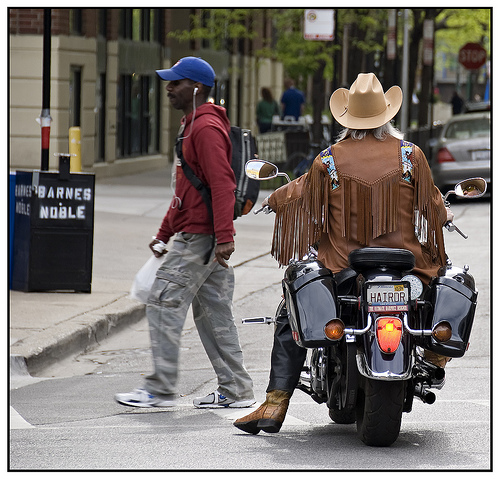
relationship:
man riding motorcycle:
[293, 82, 481, 332] [275, 243, 476, 438]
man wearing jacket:
[154, 77, 242, 261] [304, 136, 455, 255]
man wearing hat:
[154, 77, 242, 261] [328, 69, 407, 131]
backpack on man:
[218, 116, 264, 216] [149, 47, 252, 405]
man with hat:
[154, 77, 242, 261] [149, 47, 252, 405]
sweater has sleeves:
[158, 109, 250, 269] [196, 123, 247, 251]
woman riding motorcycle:
[322, 66, 415, 148] [275, 243, 476, 438]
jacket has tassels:
[304, 136, 455, 255] [267, 204, 331, 266]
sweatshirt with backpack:
[158, 109, 250, 269] [218, 116, 264, 216]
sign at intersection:
[452, 41, 487, 81] [400, 21, 487, 106]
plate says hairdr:
[360, 279, 413, 311] [362, 284, 407, 302]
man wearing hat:
[232, 70, 454, 436] [328, 69, 407, 131]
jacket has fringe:
[304, 136, 455, 255] [270, 165, 332, 265]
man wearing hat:
[154, 77, 242, 261] [154, 51, 223, 101]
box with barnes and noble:
[15, 161, 103, 292] [32, 181, 88, 226]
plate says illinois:
[360, 279, 413, 311] [373, 280, 393, 290]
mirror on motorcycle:
[437, 170, 489, 213] [275, 243, 476, 438]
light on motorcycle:
[369, 304, 396, 358] [275, 243, 476, 438]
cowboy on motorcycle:
[293, 82, 481, 332] [275, 243, 476, 438]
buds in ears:
[183, 87, 203, 140] [187, 78, 205, 96]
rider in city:
[293, 82, 481, 332] [60, 3, 461, 365]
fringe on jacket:
[270, 165, 332, 265] [304, 136, 455, 255]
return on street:
[15, 161, 103, 292] [2, 285, 111, 322]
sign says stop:
[452, 41, 487, 81] [459, 47, 481, 65]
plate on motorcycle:
[360, 279, 413, 311] [275, 243, 476, 438]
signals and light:
[316, 314, 373, 343] [369, 304, 396, 358]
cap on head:
[154, 51, 223, 101] [158, 60, 205, 113]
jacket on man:
[144, 110, 242, 264] [154, 77, 242, 261]